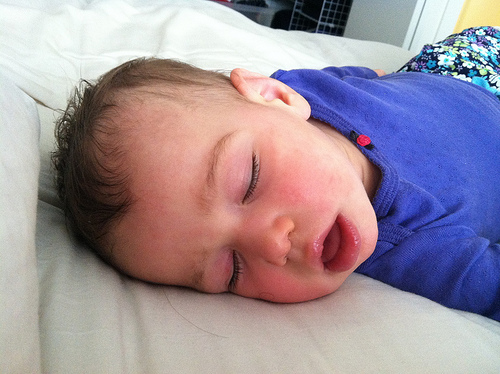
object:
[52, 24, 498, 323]
baby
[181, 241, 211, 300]
eyebrows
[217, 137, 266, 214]
eyes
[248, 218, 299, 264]
nose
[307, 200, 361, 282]
mouth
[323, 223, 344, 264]
tongue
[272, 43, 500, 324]
shirt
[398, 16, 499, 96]
shorts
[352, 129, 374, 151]
dot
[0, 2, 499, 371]
sheet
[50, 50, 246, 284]
hair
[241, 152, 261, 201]
eyelashes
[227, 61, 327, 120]
ears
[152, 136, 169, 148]
spots